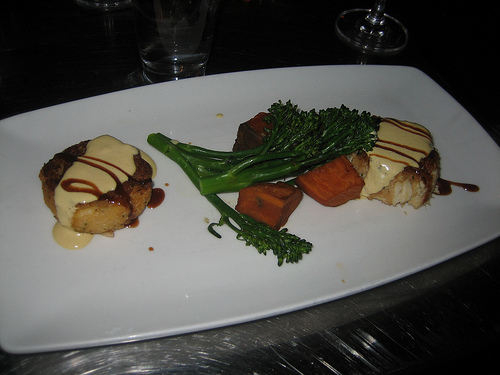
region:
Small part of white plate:
[9, 277, 106, 333]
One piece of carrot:
[235, 181, 303, 228]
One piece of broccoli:
[231, 110, 363, 186]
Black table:
[8, 42, 85, 82]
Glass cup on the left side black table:
[138, 0, 210, 70]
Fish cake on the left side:
[45, 121, 150, 226]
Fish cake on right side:
[350, 115, 442, 202]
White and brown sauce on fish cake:
[65, 145, 126, 195]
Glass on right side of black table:
[335, 0, 421, 55]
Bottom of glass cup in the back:
[83, 2, 133, 13]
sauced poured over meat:
[35, 129, 171, 251]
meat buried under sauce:
[30, 127, 163, 252]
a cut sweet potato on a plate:
[237, 174, 308, 230]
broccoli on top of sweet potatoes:
[192, 84, 387, 206]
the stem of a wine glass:
[332, 0, 412, 59]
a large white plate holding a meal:
[1, 61, 498, 355]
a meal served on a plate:
[36, 99, 477, 264]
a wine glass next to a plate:
[325, 3, 441, 61]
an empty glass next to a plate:
[127, 2, 232, 84]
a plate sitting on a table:
[3, 236, 496, 370]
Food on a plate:
[16, 131, 198, 246]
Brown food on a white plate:
[25, 126, 167, 246]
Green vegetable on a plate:
[150, 126, 296, 258]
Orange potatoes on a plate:
[236, 96, 346, 228]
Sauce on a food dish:
[347, 91, 437, 199]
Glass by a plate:
[127, 3, 249, 84]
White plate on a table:
[34, 73, 428, 333]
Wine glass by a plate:
[337, 3, 413, 69]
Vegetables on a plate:
[167, 104, 406, 259]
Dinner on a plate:
[22, 78, 497, 295]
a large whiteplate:
[6, 43, 496, 340]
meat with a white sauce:
[33, 130, 171, 238]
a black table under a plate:
[5, 248, 495, 370]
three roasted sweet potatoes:
[227, 106, 372, 236]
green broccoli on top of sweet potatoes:
[150, 95, 391, 260]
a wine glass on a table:
[330, 0, 415, 50]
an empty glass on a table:
[115, 1, 220, 79]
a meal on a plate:
[37, 103, 466, 267]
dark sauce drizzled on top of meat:
[59, 149, 141, 202]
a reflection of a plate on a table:
[6, 241, 496, 371]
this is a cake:
[68, 142, 145, 218]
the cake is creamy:
[47, 147, 144, 225]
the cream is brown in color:
[95, 156, 127, 176]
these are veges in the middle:
[213, 149, 270, 175]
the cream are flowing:
[449, 176, 487, 193]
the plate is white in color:
[36, 270, 161, 326]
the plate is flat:
[46, 262, 188, 330]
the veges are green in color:
[331, 130, 344, 135]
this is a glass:
[152, 5, 218, 61]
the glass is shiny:
[364, 17, 398, 32]